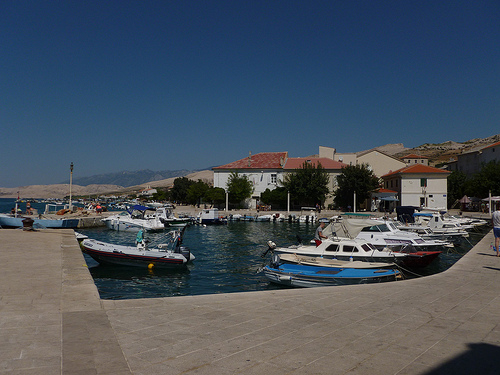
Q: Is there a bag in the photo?
A: No, there are no bags.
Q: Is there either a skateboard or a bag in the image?
A: No, there are no bags or skateboards.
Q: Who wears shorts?
A: The guy wears shorts.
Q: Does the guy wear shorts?
A: Yes, the guy wears shorts.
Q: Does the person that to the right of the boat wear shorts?
A: Yes, the guy wears shorts.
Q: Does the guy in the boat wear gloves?
A: No, the guy wears shorts.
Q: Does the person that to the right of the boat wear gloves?
A: No, the guy wears shorts.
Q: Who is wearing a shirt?
A: The guy is wearing a shirt.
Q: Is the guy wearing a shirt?
A: Yes, the guy is wearing a shirt.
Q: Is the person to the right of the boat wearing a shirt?
A: Yes, the guy is wearing a shirt.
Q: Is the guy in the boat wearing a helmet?
A: No, the guy is wearing a shirt.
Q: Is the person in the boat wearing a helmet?
A: No, the guy is wearing a shirt.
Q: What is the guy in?
A: The guy is in the boat.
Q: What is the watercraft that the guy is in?
A: The watercraft is a boat.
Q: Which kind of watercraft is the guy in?
A: The guy is in the boat.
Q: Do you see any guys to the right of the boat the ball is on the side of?
A: Yes, there is a guy to the right of the boat.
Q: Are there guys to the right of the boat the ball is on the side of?
A: Yes, there is a guy to the right of the boat.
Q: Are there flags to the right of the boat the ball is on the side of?
A: No, there is a guy to the right of the boat.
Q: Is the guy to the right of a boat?
A: Yes, the guy is to the right of a boat.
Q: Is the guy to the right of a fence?
A: No, the guy is to the right of a boat.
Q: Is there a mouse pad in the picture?
A: No, there are no mouse pads.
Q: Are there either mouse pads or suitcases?
A: No, there are no mouse pads or suitcases.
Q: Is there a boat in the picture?
A: Yes, there is a boat.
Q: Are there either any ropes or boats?
A: Yes, there is a boat.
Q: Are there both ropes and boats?
A: Yes, there are both a boat and a rope.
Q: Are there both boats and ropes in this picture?
A: Yes, there are both a boat and a rope.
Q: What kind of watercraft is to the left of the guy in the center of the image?
A: The watercraft is a boat.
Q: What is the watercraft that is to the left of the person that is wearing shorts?
A: The watercraft is a boat.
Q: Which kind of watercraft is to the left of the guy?
A: The watercraft is a boat.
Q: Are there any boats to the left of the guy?
A: Yes, there is a boat to the left of the guy.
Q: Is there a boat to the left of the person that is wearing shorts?
A: Yes, there is a boat to the left of the guy.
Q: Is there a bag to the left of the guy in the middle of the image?
A: No, there is a boat to the left of the guy.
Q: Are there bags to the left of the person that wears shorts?
A: No, there is a boat to the left of the guy.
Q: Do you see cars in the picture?
A: No, there are no cars.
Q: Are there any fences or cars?
A: No, there are no cars or fences.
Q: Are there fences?
A: No, there are no fences.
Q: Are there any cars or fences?
A: No, there are no fences or cars.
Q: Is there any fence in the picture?
A: No, there are no fences.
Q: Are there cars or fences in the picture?
A: No, there are no fences or cars.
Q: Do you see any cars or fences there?
A: No, there are no fences or cars.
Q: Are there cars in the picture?
A: No, there are no cars.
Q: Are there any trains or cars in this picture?
A: No, there are no cars or trains.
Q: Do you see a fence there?
A: No, there are no fences.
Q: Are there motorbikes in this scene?
A: No, there are no motorbikes.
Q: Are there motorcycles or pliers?
A: No, there are no motorcycles or pliers.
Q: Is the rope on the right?
A: Yes, the rope is on the right of the image.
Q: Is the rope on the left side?
A: No, the rope is on the right of the image.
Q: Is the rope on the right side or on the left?
A: The rope is on the right of the image.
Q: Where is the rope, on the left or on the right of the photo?
A: The rope is on the right of the image.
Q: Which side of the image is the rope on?
A: The rope is on the right of the image.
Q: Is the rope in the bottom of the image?
A: Yes, the rope is in the bottom of the image.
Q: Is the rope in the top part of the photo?
A: No, the rope is in the bottom of the image.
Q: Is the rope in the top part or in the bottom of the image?
A: The rope is in the bottom of the image.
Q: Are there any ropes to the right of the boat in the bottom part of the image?
A: Yes, there is a rope to the right of the boat.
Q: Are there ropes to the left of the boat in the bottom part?
A: No, the rope is to the right of the boat.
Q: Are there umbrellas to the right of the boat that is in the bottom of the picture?
A: No, there is a rope to the right of the boat.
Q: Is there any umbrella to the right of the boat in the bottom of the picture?
A: No, there is a rope to the right of the boat.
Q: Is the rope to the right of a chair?
A: No, the rope is to the right of the boat.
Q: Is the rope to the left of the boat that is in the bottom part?
A: No, the rope is to the right of the boat.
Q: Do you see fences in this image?
A: No, there are no fences.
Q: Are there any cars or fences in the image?
A: No, there are no fences or cars.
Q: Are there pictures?
A: No, there are no pictures.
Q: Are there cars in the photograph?
A: No, there are no cars.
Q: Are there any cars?
A: No, there are no cars.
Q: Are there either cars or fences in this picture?
A: No, there are no cars or fences.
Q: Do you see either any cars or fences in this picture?
A: No, there are no cars or fences.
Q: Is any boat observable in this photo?
A: Yes, there is a boat.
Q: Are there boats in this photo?
A: Yes, there is a boat.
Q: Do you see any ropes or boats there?
A: Yes, there is a boat.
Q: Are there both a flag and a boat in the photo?
A: No, there is a boat but no flags.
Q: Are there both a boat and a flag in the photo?
A: No, there is a boat but no flags.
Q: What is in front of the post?
A: The boat is in front of the post.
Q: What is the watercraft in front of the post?
A: The watercraft is a boat.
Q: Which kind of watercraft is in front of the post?
A: The watercraft is a boat.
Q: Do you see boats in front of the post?
A: Yes, there is a boat in front of the post.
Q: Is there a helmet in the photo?
A: No, there are no helmets.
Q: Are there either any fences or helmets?
A: No, there are no helmets or fences.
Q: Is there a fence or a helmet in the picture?
A: No, there are no helmets or fences.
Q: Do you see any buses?
A: No, there are no buses.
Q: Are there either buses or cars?
A: No, there are no buses or cars.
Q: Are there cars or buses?
A: No, there are no buses or cars.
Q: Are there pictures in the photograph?
A: No, there are no pictures.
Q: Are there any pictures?
A: No, there are no pictures.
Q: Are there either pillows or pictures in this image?
A: No, there are no pictures or pillows.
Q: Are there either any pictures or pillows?
A: No, there are no pictures or pillows.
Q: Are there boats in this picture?
A: Yes, there is a boat.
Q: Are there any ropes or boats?
A: Yes, there is a boat.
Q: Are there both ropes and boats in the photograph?
A: Yes, there are both a boat and a rope.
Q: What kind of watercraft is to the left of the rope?
A: The watercraft is a boat.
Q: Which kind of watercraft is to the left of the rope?
A: The watercraft is a boat.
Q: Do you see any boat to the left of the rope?
A: Yes, there is a boat to the left of the rope.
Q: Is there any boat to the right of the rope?
A: No, the boat is to the left of the rope.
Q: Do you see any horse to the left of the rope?
A: No, there is a boat to the left of the rope.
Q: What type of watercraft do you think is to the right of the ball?
A: The watercraft is a boat.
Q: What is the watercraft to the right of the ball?
A: The watercraft is a boat.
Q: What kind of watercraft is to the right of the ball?
A: The watercraft is a boat.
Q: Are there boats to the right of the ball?
A: Yes, there is a boat to the right of the ball.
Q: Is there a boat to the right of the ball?
A: Yes, there is a boat to the right of the ball.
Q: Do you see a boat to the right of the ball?
A: Yes, there is a boat to the right of the ball.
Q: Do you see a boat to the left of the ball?
A: No, the boat is to the right of the ball.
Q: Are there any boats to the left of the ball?
A: No, the boat is to the right of the ball.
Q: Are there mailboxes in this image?
A: No, there are no mailboxes.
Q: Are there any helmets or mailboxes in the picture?
A: No, there are no mailboxes or helmets.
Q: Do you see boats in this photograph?
A: Yes, there is a boat.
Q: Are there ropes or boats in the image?
A: Yes, there is a boat.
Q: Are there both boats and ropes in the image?
A: Yes, there are both a boat and a rope.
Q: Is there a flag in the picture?
A: No, there are no flags.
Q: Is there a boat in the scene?
A: Yes, there is a boat.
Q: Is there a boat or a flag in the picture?
A: Yes, there is a boat.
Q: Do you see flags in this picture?
A: No, there are no flags.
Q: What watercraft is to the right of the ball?
A: The watercraft is a boat.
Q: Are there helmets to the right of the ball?
A: No, there is a boat to the right of the ball.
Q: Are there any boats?
A: Yes, there is a boat.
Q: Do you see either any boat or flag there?
A: Yes, there is a boat.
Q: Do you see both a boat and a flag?
A: No, there is a boat but no flags.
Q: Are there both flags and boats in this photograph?
A: No, there is a boat but no flags.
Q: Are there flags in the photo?
A: No, there are no flags.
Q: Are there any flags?
A: No, there are no flags.